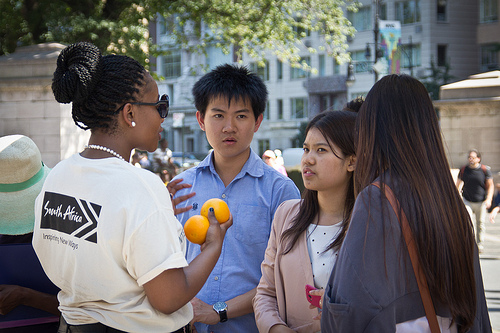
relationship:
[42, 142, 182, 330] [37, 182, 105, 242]
shirt on picture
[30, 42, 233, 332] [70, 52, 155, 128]
lady has braids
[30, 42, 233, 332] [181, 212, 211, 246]
lady holds orange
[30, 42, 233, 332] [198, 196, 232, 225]
lady holds orange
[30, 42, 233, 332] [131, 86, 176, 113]
lady wears sunglasses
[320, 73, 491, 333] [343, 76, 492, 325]
lady has hair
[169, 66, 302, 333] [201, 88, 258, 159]
man has face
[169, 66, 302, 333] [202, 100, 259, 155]
man has face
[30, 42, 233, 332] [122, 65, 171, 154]
lady has face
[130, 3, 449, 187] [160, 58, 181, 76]
building has window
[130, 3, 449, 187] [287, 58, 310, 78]
building has window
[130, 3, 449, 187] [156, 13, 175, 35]
building has window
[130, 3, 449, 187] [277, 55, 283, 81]
building has window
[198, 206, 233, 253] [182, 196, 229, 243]
hand holds oranges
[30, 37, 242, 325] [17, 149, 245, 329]
lady wears tee shirt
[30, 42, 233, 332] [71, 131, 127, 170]
lady wears pearls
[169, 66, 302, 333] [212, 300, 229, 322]
man wears watch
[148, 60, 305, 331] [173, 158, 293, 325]
man wears shirt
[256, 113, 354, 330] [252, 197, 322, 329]
lady wearing beige cardigan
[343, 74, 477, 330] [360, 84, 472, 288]
black hair on lady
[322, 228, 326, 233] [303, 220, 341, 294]
dot on shirt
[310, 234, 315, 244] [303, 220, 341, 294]
dot on shirt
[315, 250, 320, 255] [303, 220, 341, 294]
dot on shirt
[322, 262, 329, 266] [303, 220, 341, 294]
dot on shirt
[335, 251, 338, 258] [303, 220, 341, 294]
dot on shirt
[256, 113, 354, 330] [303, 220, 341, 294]
lady wearing shirt